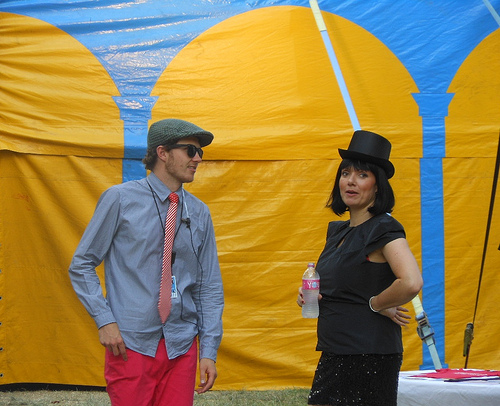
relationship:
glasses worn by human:
[167, 139, 208, 159] [59, 113, 229, 403]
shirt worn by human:
[314, 211, 413, 357] [300, 122, 440, 403]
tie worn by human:
[150, 193, 185, 326] [59, 113, 229, 403]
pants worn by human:
[100, 328, 199, 404] [59, 113, 229, 403]